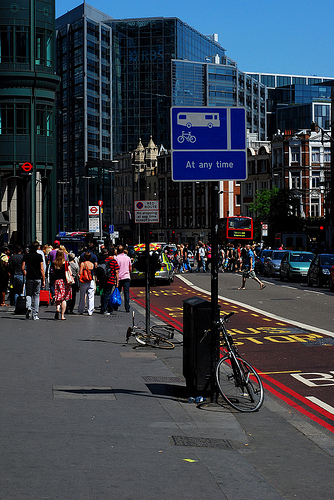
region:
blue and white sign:
[180, 114, 239, 184]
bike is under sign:
[204, 306, 268, 429]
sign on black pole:
[202, 172, 225, 315]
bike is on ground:
[117, 331, 180, 368]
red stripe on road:
[153, 299, 328, 439]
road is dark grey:
[19, 348, 126, 479]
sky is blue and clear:
[250, 0, 324, 72]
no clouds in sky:
[244, 18, 324, 78]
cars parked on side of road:
[259, 241, 330, 289]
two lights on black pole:
[130, 128, 168, 189]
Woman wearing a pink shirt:
[110, 243, 138, 313]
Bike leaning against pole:
[202, 309, 277, 413]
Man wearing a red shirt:
[99, 245, 124, 318]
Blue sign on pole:
[163, 95, 265, 398]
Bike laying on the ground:
[120, 306, 175, 353]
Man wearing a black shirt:
[19, 244, 43, 322]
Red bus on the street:
[219, 210, 259, 250]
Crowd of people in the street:
[156, 238, 261, 275]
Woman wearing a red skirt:
[46, 249, 75, 320]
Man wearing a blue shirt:
[237, 243, 265, 291]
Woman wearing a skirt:
[54, 275, 74, 303]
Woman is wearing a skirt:
[51, 276, 72, 300]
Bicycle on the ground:
[121, 309, 181, 351]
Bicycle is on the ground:
[125, 309, 178, 356]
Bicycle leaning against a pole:
[200, 309, 265, 419]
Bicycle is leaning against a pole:
[192, 310, 266, 414]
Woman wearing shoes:
[52, 308, 67, 324]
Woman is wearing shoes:
[51, 307, 71, 322]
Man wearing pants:
[24, 273, 43, 322]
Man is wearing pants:
[23, 275, 40, 320]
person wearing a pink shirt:
[111, 242, 135, 311]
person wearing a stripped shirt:
[99, 250, 120, 311]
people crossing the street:
[189, 235, 279, 289]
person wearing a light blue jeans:
[19, 234, 47, 324]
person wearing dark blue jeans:
[108, 243, 137, 311]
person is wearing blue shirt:
[238, 243, 267, 293]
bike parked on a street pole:
[200, 309, 274, 413]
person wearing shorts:
[230, 242, 266, 290]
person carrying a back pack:
[92, 245, 120, 317]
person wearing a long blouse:
[48, 247, 79, 319]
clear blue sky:
[229, 4, 329, 40]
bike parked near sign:
[178, 296, 265, 412]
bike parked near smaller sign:
[124, 313, 175, 348]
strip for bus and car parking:
[151, 281, 206, 306]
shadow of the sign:
[55, 379, 187, 408]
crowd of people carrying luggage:
[11, 241, 131, 306]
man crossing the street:
[236, 244, 264, 290]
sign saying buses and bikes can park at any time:
[170, 105, 249, 183]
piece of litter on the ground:
[182, 455, 194, 464]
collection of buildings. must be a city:
[64, 8, 331, 108]